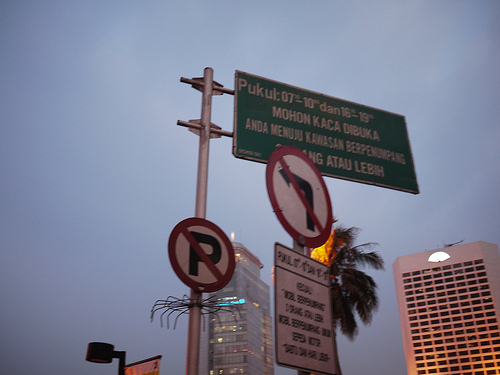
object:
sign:
[232, 69, 419, 195]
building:
[391, 239, 498, 375]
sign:
[265, 145, 333, 248]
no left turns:
[278, 165, 316, 233]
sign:
[167, 217, 235, 293]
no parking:
[189, 231, 222, 276]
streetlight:
[85, 341, 125, 366]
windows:
[453, 269, 464, 275]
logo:
[428, 251, 451, 263]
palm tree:
[326, 218, 386, 342]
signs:
[175, 66, 419, 375]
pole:
[184, 67, 215, 375]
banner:
[125, 357, 162, 374]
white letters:
[239, 78, 405, 177]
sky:
[0, 0, 500, 375]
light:
[216, 296, 245, 306]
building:
[197, 231, 274, 375]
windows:
[221, 325, 237, 332]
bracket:
[177, 66, 234, 140]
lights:
[207, 232, 275, 375]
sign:
[274, 242, 340, 375]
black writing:
[278, 250, 333, 363]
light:
[310, 227, 334, 267]